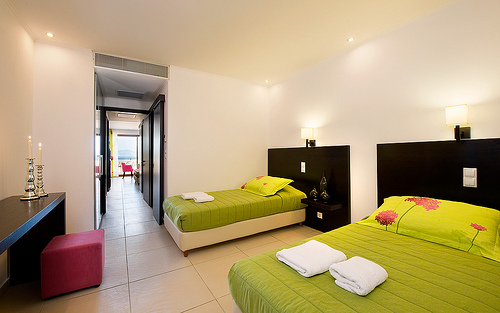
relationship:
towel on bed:
[177, 189, 217, 206] [157, 179, 308, 256]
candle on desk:
[16, 129, 40, 203] [0, 190, 73, 310]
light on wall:
[443, 103, 473, 141] [266, 5, 483, 249]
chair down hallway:
[118, 158, 136, 178] [96, 73, 166, 232]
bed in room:
[157, 179, 308, 256] [3, 2, 483, 311]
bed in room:
[223, 191, 482, 310] [3, 2, 483, 311]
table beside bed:
[297, 188, 345, 236] [157, 179, 308, 256]